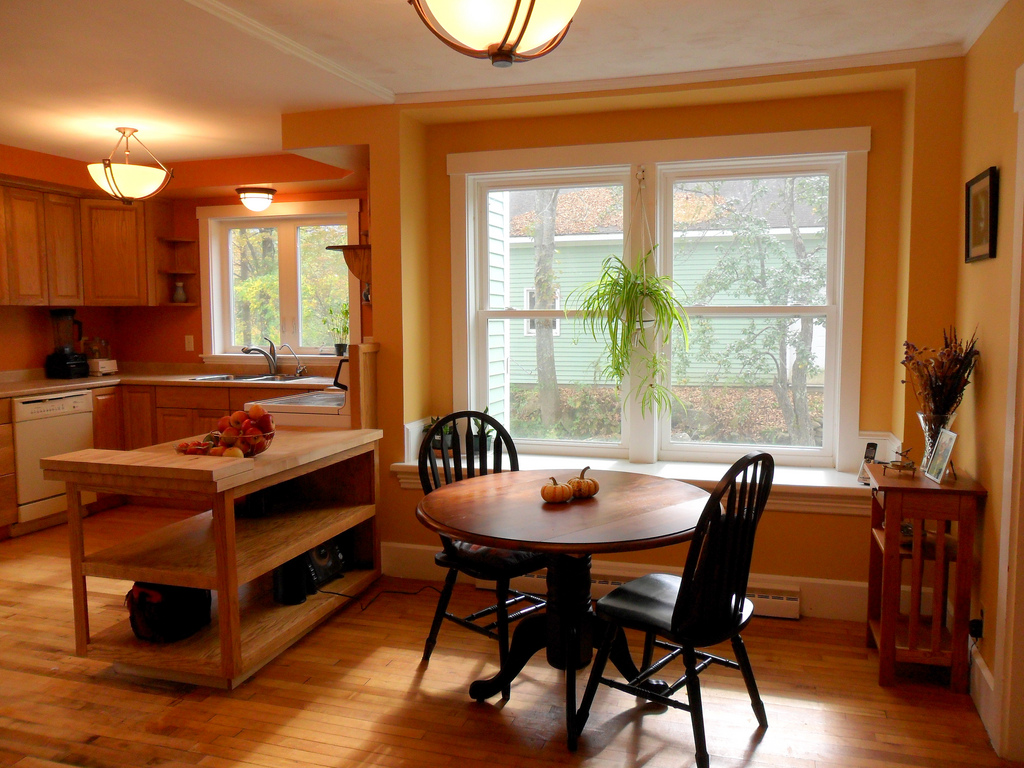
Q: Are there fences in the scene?
A: No, there are no fences.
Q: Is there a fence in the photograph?
A: No, there are no fences.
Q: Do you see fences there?
A: No, there are no fences.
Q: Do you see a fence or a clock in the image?
A: No, there are no fences or clocks.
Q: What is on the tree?
A: The leaves are on the tree.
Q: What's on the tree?
A: The leaves are on the tree.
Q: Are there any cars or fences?
A: No, there are no fences or cars.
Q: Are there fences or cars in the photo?
A: No, there are no fences or cars.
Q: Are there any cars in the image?
A: No, there are no cars.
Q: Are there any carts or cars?
A: No, there are no cars or carts.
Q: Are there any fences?
A: No, there are no fences.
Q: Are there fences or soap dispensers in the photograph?
A: No, there are no fences or soap dispensers.